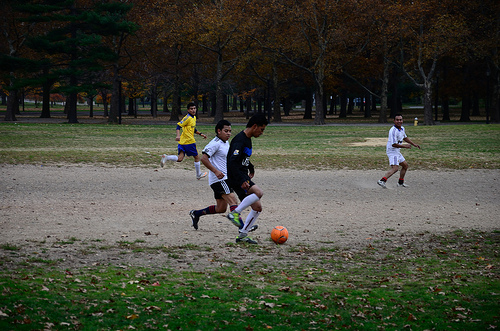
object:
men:
[160, 103, 208, 181]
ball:
[270, 226, 289, 244]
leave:
[228, 250, 279, 302]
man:
[224, 114, 266, 245]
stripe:
[63, 148, 105, 152]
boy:
[376, 114, 420, 189]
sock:
[236, 194, 259, 213]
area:
[0, 101, 500, 331]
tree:
[4, 0, 58, 122]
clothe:
[203, 136, 234, 186]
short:
[177, 141, 198, 157]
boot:
[227, 210, 244, 227]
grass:
[241, 293, 305, 329]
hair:
[215, 119, 231, 134]